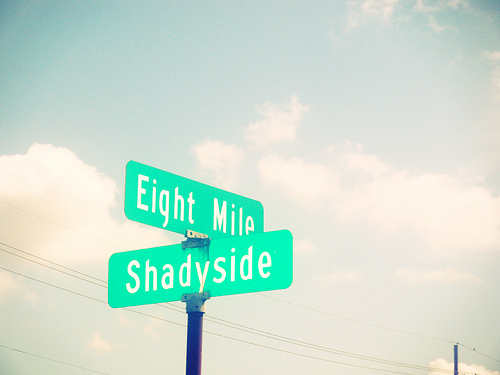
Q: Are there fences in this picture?
A: No, there are no fences.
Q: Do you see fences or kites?
A: No, there are no fences or kites.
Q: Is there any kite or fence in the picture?
A: No, there are no fences or kites.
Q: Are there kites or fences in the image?
A: No, there are no fences or kites.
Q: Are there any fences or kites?
A: No, there are no fences or kites.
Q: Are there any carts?
A: No, there are no carts.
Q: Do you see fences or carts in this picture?
A: No, there are no carts or fences.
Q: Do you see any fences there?
A: No, there are no fences.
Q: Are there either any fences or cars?
A: No, there are no fences or cars.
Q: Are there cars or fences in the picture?
A: No, there are no fences or cars.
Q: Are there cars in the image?
A: No, there are no cars.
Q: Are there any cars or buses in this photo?
A: No, there are no cars or buses.